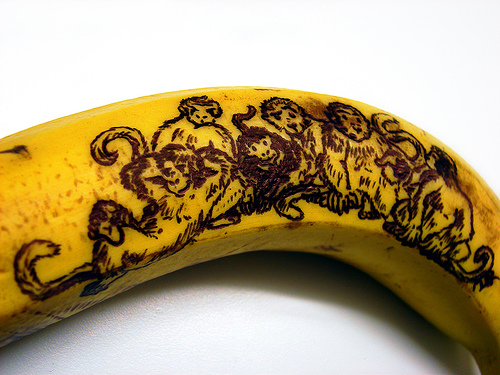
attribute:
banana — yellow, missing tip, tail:
[13, 77, 497, 318]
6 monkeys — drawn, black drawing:
[101, 120, 463, 237]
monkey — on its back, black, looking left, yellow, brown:
[112, 148, 211, 240]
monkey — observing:
[153, 98, 236, 159]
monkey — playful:
[230, 112, 297, 216]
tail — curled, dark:
[13, 226, 85, 304]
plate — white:
[188, 307, 382, 361]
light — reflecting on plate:
[223, 308, 330, 344]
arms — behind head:
[135, 160, 239, 189]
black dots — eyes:
[248, 139, 277, 150]